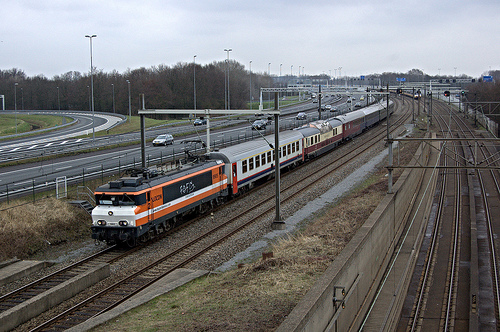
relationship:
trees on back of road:
[0, 69, 258, 120] [1, 87, 355, 215]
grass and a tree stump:
[114, 171, 384, 331] [260, 248, 277, 266]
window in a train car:
[238, 158, 250, 174] [201, 128, 304, 195]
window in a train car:
[251, 157, 255, 170] [201, 128, 304, 195]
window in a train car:
[260, 150, 267, 170] [201, 128, 304, 195]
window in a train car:
[265, 150, 275, 162] [201, 128, 304, 195]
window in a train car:
[277, 147, 287, 161] [201, 128, 304, 195]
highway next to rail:
[0, 88, 377, 193] [3, 86, 420, 330]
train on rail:
[90, 99, 390, 246] [3, 86, 420, 330]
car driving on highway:
[132, 130, 179, 164] [10, 100, 140, 176]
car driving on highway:
[248, 113, 273, 131] [10, 100, 140, 176]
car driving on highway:
[181, 113, 210, 136] [10, 100, 140, 176]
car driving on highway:
[282, 99, 316, 135] [10, 100, 140, 176]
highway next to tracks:
[0, 88, 377, 193] [387, 162, 499, 253]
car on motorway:
[148, 128, 180, 150] [110, 120, 193, 158]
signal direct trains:
[330, 281, 352, 311] [103, 93, 408, 250]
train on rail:
[90, 99, 390, 246] [391, 96, 499, 330]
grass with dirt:
[229, 252, 294, 294] [188, 297, 276, 325]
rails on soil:
[128, 97, 293, 223] [267, 196, 382, 274]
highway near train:
[0, 88, 377, 193] [90, 99, 390, 246]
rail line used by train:
[124, 281, 158, 297] [88, 146, 259, 249]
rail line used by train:
[37, 260, 70, 280] [88, 146, 259, 249]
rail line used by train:
[126, 263, 161, 280] [88, 146, 259, 249]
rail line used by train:
[104, 249, 129, 269] [88, 146, 259, 249]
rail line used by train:
[167, 239, 200, 259] [88, 146, 259, 249]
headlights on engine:
[93, 212, 142, 228] [87, 151, 229, 250]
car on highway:
[148, 128, 180, 150] [0, 88, 377, 193]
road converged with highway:
[0, 111, 120, 164] [0, 88, 377, 193]